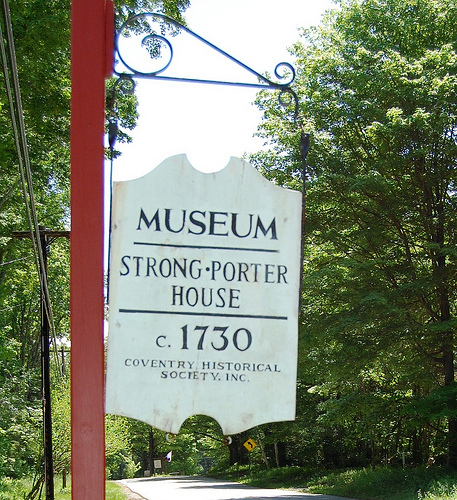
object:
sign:
[103, 154, 306, 437]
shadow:
[180, 468, 301, 491]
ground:
[99, 472, 457, 499]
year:
[155, 320, 255, 354]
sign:
[240, 438, 258, 452]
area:
[246, 440, 256, 449]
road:
[114, 476, 350, 498]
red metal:
[67, 1, 123, 499]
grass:
[416, 487, 457, 499]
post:
[68, 0, 114, 498]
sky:
[103, 0, 363, 336]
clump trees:
[242, 0, 457, 470]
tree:
[130, 415, 172, 476]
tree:
[183, 412, 253, 466]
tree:
[132, 384, 212, 455]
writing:
[124, 354, 283, 385]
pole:
[35, 232, 56, 499]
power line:
[0, 6, 65, 379]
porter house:
[169, 251, 293, 318]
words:
[133, 206, 279, 244]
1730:
[179, 324, 255, 353]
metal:
[114, 10, 296, 89]